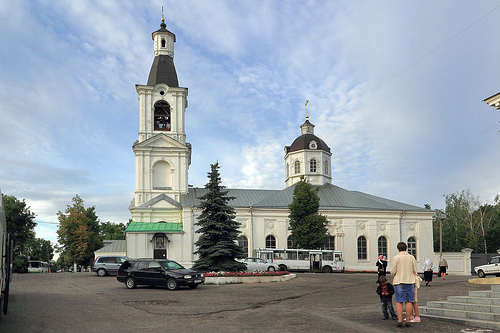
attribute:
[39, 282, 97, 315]
street — black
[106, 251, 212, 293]
car — black, gray, white, parked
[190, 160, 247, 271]
tree — large, pine, pointy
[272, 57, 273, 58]
clouds — white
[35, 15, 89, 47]
sky — blue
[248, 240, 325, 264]
bus — green, parked, leaving, white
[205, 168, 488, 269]
church — large, white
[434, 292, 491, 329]
steps — gray, four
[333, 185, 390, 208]
roof — silver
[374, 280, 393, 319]
boy — walking, small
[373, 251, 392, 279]
woman — walking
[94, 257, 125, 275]
van — blue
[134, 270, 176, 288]
station wagon — black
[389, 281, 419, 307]
shorts — blue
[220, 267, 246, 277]
flowers — red